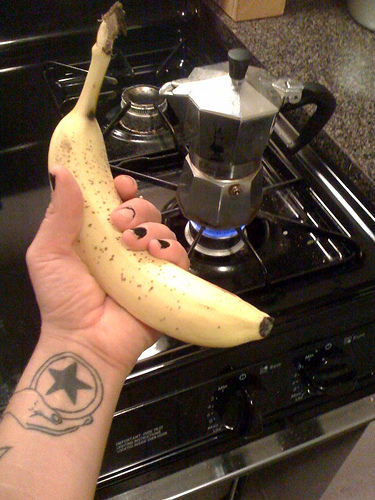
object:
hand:
[25, 166, 193, 376]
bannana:
[45, 0, 275, 351]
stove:
[38, 35, 375, 490]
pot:
[158, 46, 337, 231]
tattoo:
[0, 349, 103, 458]